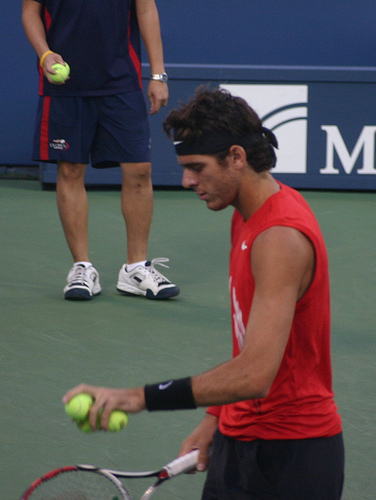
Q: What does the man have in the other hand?
A: Racket.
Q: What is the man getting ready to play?
A: Tennis.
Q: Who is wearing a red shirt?
A: A man.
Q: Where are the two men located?
A: Tennis court.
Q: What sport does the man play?
A: Tennis.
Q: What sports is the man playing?
A: Tennis.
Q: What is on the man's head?
A: Headband.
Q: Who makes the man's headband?
A: Nike.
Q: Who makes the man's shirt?
A: Nike.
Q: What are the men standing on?
A: Court.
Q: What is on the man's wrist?
A: Wristband.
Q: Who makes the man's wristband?
A: Nike.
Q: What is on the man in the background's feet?
A: Tennis shoes.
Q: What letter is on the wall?
A: M.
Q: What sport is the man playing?
A: Tennis.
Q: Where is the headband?
A: On the tennis player's head.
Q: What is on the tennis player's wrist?
A: A wristband.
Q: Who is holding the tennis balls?
A: Tennis players.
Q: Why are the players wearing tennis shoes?
A: Playing tennis.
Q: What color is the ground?
A: Dark green.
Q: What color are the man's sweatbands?
A: Black.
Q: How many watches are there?
A: One.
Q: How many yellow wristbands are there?
A: One.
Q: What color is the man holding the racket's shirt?
A: Red.